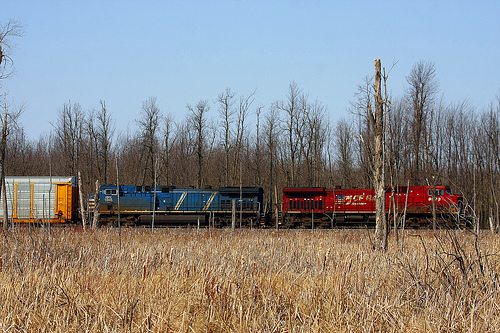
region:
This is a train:
[4, 155, 471, 235]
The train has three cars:
[17, 166, 465, 221]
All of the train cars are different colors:
[7, 160, 469, 225]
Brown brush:
[8, 230, 485, 321]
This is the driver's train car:
[287, 175, 469, 227]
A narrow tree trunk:
[356, 59, 402, 249]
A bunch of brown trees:
[17, 81, 489, 191]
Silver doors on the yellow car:
[6, 180, 71, 220]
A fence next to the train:
[49, 196, 391, 231]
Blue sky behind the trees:
[27, 12, 467, 139]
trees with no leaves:
[85, 93, 456, 162]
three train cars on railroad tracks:
[5, 175, 475, 231]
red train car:
[287, 172, 462, 229]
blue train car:
[87, 172, 263, 228]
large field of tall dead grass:
[7, 224, 479, 323]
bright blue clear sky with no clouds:
[59, 11, 259, 76]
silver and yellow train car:
[5, 172, 89, 225]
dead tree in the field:
[358, 61, 400, 252]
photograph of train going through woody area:
[8, 10, 488, 322]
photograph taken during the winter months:
[19, 39, 481, 312]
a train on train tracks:
[179, 100, 499, 231]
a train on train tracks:
[129, 163, 400, 258]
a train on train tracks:
[248, 145, 454, 255]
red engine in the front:
[278, 184, 475, 210]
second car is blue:
[86, 181, 266, 227]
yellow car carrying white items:
[1, 186, 73, 217]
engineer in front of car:
[432, 188, 442, 198]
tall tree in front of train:
[355, 100, 389, 266]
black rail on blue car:
[219, 204, 260, 219]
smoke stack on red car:
[329, 173, 347, 195]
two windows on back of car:
[101, 187, 122, 204]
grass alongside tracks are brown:
[8, 242, 499, 332]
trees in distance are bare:
[1, 100, 355, 173]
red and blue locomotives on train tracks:
[98, 179, 493, 234]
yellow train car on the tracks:
[1, 173, 88, 220]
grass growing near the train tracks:
[102, 217, 428, 324]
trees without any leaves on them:
[158, 100, 468, 170]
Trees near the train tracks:
[128, 112, 472, 185]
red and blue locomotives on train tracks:
[177, 183, 376, 218]